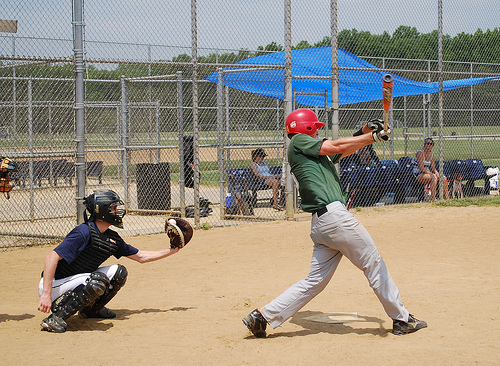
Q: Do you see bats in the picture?
A: Yes, there is a bat.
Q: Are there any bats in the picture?
A: Yes, there is a bat.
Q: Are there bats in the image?
A: Yes, there is a bat.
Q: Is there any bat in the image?
A: Yes, there is a bat.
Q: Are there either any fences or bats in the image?
A: Yes, there is a bat.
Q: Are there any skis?
A: No, there are no skis.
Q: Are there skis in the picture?
A: No, there are no skis.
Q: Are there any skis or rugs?
A: No, there are no skis or rugs.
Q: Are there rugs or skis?
A: No, there are no skis or rugs.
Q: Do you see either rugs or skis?
A: No, there are no skis or rugs.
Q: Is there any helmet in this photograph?
A: Yes, there is a helmet.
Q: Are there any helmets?
A: Yes, there is a helmet.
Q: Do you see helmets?
A: Yes, there is a helmet.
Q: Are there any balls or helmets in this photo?
A: Yes, there is a helmet.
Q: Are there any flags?
A: No, there are no flags.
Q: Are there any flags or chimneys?
A: No, there are no flags or chimneys.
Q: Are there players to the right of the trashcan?
A: Yes, there is a player to the right of the trashcan.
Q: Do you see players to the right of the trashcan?
A: Yes, there is a player to the right of the trashcan.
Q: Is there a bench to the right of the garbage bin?
A: No, there is a player to the right of the garbage bin.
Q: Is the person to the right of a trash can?
A: Yes, the player is to the right of a trash can.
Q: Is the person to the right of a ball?
A: No, the player is to the right of a trash can.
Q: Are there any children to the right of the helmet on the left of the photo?
A: No, there is a player to the right of the helmet.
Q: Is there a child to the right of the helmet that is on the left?
A: No, there is a player to the right of the helmet.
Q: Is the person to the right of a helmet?
A: Yes, the player is to the right of a helmet.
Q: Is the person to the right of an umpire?
A: No, the player is to the right of a helmet.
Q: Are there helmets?
A: Yes, there is a helmet.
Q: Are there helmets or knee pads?
A: Yes, there is a helmet.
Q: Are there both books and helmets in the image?
A: No, there is a helmet but no books.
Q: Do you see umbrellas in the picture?
A: No, there are no umbrellas.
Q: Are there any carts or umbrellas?
A: No, there are no umbrellas or carts.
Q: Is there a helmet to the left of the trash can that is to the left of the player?
A: Yes, there is a helmet to the left of the trash can.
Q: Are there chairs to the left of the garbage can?
A: No, there is a helmet to the left of the garbage can.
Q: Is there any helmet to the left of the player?
A: Yes, there is a helmet to the left of the player.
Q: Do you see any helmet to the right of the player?
A: No, the helmet is to the left of the player.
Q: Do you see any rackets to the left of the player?
A: No, there is a helmet to the left of the player.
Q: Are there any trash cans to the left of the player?
A: Yes, there is a trash can to the left of the player.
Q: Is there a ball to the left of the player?
A: No, there is a trash can to the left of the player.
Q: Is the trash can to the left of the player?
A: Yes, the trash can is to the left of the player.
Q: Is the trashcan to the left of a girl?
A: No, the trashcan is to the left of the player.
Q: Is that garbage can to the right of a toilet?
A: No, the garbage can is to the right of the helmet.